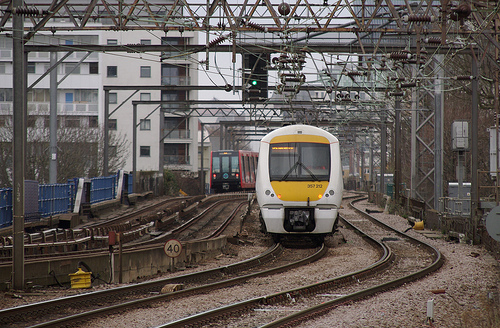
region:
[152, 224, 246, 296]
the km sign is round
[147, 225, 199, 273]
the km sign is round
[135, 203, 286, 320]
the km sign is round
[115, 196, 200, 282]
the km sign is round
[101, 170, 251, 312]
the km sign is round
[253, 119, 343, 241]
a white and yellow train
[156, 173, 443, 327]
a curving railroad track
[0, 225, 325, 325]
a curving railroad track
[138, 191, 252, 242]
a curving railroad track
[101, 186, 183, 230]
a curving railroad track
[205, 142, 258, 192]
a red and black train in distance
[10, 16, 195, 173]
a tall light brown buliding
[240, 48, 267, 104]
an electronic train signal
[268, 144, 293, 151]
a train destination sign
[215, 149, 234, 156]
a train destination sign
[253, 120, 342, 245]
the front of a train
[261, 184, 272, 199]
the head light of a train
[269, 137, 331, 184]
a glass windshield on the train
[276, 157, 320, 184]
a pair of windshield wipers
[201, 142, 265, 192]
a train on the tracks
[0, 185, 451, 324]
sets of train tracks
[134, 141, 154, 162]
a window on the building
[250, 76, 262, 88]
a green traffic light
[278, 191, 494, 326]
gravel next to the train tracks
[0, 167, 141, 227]
a blue metal fence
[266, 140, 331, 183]
the front window of a train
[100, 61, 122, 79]
a window in a building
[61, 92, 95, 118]
the walk of a building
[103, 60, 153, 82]
the windows of a building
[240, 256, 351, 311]
multiple train tracks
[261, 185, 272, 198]
the lights on a train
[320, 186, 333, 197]
the lights on a train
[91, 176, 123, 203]
a blue railing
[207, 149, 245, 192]
the front of a train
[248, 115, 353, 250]
This is a train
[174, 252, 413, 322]
These are train tracks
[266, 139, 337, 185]
The train's windshield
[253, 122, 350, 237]
The train is yellow and white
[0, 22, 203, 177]
An apartment building is in the background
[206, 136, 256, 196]
Another train is here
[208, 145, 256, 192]
This train is red and black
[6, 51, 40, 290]
A steel beam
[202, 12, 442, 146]
Electric wires are above the train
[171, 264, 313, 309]
Gravel is between the tracks